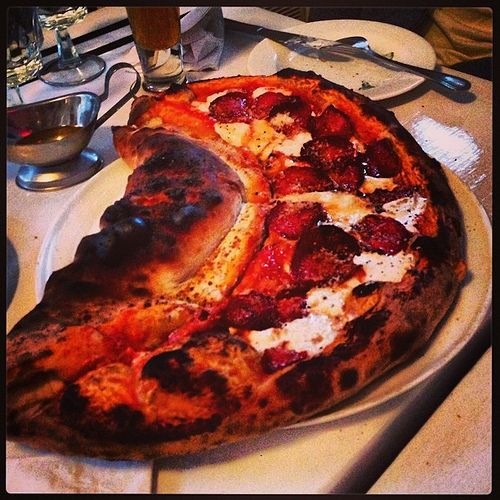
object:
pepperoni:
[302, 137, 354, 172]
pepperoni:
[291, 226, 361, 278]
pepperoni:
[352, 213, 410, 254]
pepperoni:
[364, 140, 400, 178]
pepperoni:
[306, 106, 353, 140]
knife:
[222, 18, 352, 62]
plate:
[247, 20, 436, 100]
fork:
[323, 36, 471, 91]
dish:
[34, 158, 492, 430]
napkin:
[5, 435, 155, 496]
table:
[8, 4, 492, 499]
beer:
[123, 7, 180, 50]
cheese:
[249, 289, 346, 356]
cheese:
[281, 192, 371, 231]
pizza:
[7, 66, 466, 463]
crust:
[427, 216, 459, 279]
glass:
[122, 4, 189, 94]